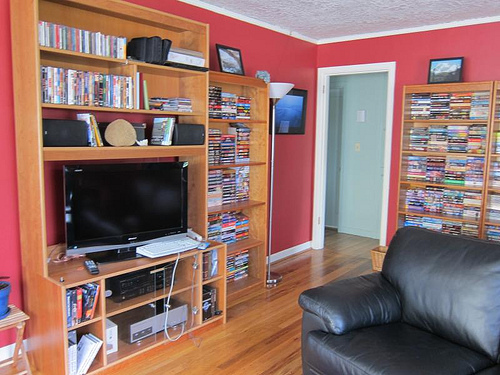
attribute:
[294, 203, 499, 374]
sofa — leather, black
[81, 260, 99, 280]
control — remote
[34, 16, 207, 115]
books — stacked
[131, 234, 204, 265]
keyboard — white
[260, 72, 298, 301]
lamp — white, silver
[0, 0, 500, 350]
wall — pink, dark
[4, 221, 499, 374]
floor — wood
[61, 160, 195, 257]
screen — tv, flat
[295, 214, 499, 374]
couch — leather, black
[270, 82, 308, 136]
portrait — blue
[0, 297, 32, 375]
table — wooden, folding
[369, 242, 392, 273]
can — trash, woven